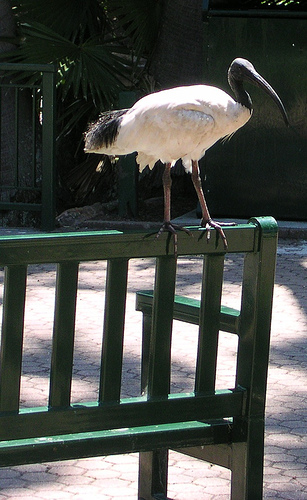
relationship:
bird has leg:
[85, 53, 292, 256] [189, 158, 215, 224]